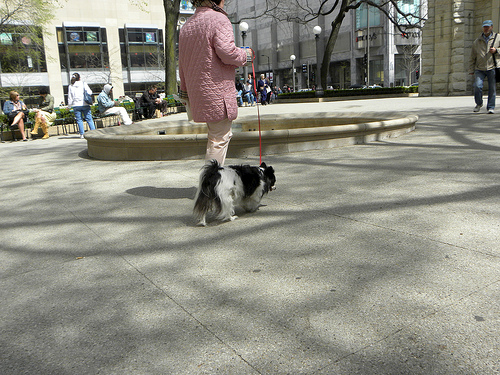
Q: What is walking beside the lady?
A: A small dog.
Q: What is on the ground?
A: Shadows.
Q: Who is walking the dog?
A: The woman.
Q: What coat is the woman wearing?
A: A pink coat.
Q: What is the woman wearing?
A: A pink coat.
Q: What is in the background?
A: A bare tree.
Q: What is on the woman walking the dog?
A: The pink jacket.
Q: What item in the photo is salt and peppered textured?
A: The concrete sidewalk slab.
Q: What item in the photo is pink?
A: The heavy winter coat.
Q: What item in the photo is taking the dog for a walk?
A: The woman.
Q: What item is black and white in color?
A: The dog.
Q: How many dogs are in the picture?
A: One.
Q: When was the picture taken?
A: During the day.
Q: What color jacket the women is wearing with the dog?
A: Pink.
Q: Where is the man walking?
A: Toward the women.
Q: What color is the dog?
A: Black and white.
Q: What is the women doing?
A: Walking the dog.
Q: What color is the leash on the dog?
A: Red.